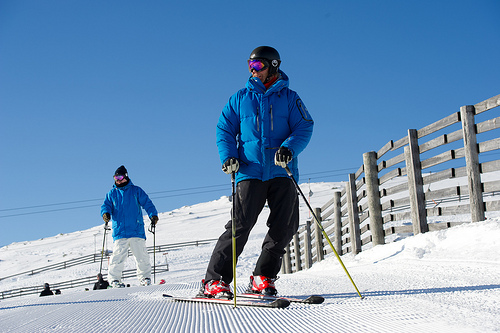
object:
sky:
[3, 1, 499, 241]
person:
[200, 44, 347, 324]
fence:
[270, 103, 499, 274]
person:
[94, 162, 161, 290]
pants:
[105, 233, 157, 283]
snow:
[13, 177, 498, 332]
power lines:
[3, 193, 105, 213]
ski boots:
[243, 271, 280, 299]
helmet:
[245, 46, 286, 84]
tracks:
[73, 277, 92, 328]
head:
[245, 43, 279, 87]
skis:
[174, 277, 290, 316]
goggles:
[247, 60, 270, 74]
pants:
[204, 165, 308, 282]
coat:
[215, 67, 314, 184]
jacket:
[98, 183, 160, 240]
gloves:
[217, 155, 244, 176]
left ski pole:
[96, 206, 110, 289]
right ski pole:
[141, 221, 176, 287]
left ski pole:
[226, 156, 246, 312]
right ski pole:
[281, 159, 370, 299]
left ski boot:
[196, 269, 241, 301]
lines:
[148, 299, 159, 332]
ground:
[25, 221, 499, 317]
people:
[34, 279, 54, 299]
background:
[6, 101, 499, 285]